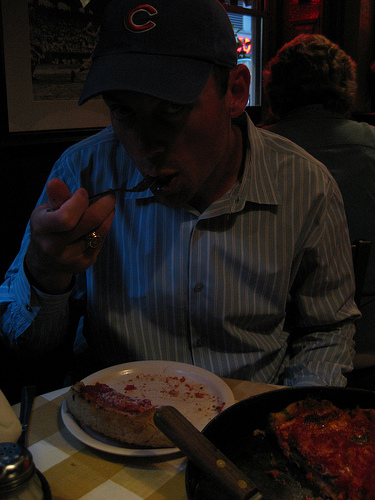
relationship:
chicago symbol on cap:
[124, 5, 160, 30] [72, 0, 242, 112]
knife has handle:
[139, 415, 335, 494] [155, 407, 249, 494]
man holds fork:
[1, 19, 363, 408] [61, 161, 206, 215]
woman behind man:
[256, 37, 366, 239] [1, 19, 363, 408]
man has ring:
[1, 19, 363, 408] [74, 227, 107, 251]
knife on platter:
[139, 415, 335, 494] [192, 333, 375, 499]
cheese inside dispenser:
[14, 479, 48, 498] [10, 439, 40, 498]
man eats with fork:
[1, 19, 363, 408] [61, 161, 206, 215]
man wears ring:
[1, 19, 363, 408] [74, 227, 107, 251]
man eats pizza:
[1, 19, 363, 408] [63, 335, 216, 491]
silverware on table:
[20, 383, 58, 462] [10, 385, 190, 493]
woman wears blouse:
[256, 37, 366, 239] [282, 107, 372, 230]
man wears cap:
[1, 19, 363, 408] [72, 0, 242, 112]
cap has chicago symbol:
[72, 0, 242, 112] [124, 5, 160, 30]